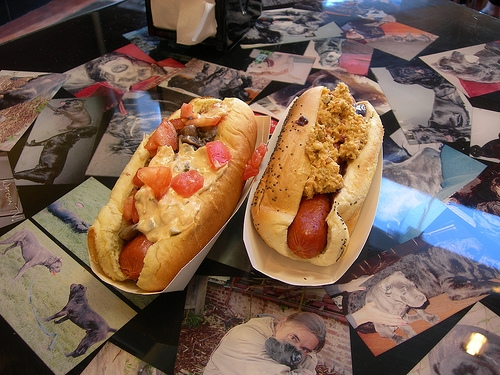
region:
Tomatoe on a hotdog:
[133, 128, 220, 205]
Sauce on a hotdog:
[302, 81, 380, 203]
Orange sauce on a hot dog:
[127, 106, 222, 283]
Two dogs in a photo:
[3, 225, 139, 374]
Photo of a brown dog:
[36, 89, 99, 131]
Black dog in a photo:
[162, 60, 267, 110]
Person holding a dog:
[223, 306, 331, 374]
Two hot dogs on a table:
[83, 85, 412, 326]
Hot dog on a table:
[241, 76, 389, 316]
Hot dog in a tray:
[86, 83, 273, 291]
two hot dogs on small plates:
[80, 71, 407, 308]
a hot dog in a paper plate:
[250, 76, 394, 296]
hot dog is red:
[287, 188, 336, 265]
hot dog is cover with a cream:
[283, 70, 369, 270]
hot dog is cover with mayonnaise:
[80, 83, 260, 304]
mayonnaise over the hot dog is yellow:
[117, 134, 229, 241]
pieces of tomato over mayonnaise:
[114, 96, 236, 212]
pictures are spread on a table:
[13, 0, 498, 373]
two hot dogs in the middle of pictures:
[80, 67, 405, 319]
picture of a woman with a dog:
[183, 289, 360, 373]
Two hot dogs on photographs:
[64, 50, 453, 352]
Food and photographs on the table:
[37, 21, 482, 362]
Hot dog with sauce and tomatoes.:
[92, 81, 256, 291]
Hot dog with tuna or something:
[259, 88, 393, 273]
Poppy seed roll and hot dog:
[256, 71, 320, 250]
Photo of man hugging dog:
[222, 296, 362, 373]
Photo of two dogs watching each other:
[7, 196, 113, 373]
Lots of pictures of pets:
[3, 30, 182, 373]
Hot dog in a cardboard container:
[246, 75, 395, 307]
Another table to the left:
[1, 2, 153, 71]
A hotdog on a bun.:
[81, 81, 264, 301]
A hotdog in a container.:
[78, 65, 270, 313]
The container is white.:
[90, 81, 280, 321]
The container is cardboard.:
[71, 63, 278, 309]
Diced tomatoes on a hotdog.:
[91, 75, 262, 299]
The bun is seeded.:
[260, 72, 390, 294]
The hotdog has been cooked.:
[247, 72, 390, 293]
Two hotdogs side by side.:
[68, 68, 403, 305]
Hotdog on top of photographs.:
[0, 36, 499, 373]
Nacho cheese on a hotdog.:
[81, 67, 277, 304]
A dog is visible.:
[326, 247, 428, 344]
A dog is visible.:
[337, 293, 403, 373]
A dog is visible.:
[361, 218, 420, 348]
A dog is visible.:
[350, 219, 407, 312]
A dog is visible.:
[386, 221, 440, 331]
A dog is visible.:
[343, 259, 403, 341]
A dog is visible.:
[380, 286, 431, 349]